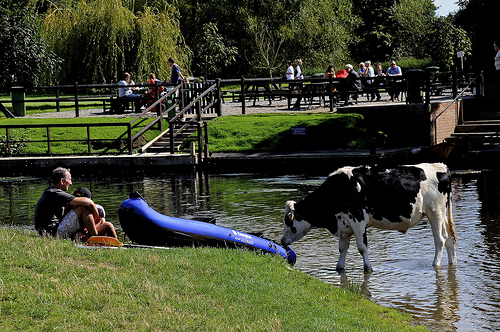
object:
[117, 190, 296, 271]
raft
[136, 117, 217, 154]
stairway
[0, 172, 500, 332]
water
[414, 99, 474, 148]
wall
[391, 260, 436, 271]
reflection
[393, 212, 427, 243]
ground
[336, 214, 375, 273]
legs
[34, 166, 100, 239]
man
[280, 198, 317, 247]
head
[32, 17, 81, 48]
leaves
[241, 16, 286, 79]
trees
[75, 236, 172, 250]
oar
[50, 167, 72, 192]
head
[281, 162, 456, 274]
cow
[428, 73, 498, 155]
stairway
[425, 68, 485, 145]
rail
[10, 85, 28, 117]
trash can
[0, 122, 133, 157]
fence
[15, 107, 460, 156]
hill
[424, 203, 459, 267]
legs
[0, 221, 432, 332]
grass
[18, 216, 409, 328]
ground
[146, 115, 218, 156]
steps